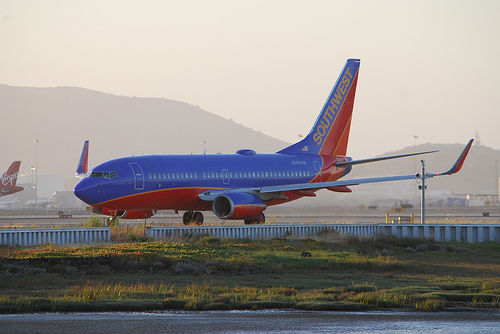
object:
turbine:
[211, 193, 234, 219]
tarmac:
[0, 206, 500, 225]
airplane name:
[311, 67, 357, 146]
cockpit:
[89, 171, 118, 179]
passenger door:
[129, 162, 145, 191]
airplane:
[73, 58, 475, 225]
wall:
[0, 173, 88, 211]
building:
[0, 182, 87, 212]